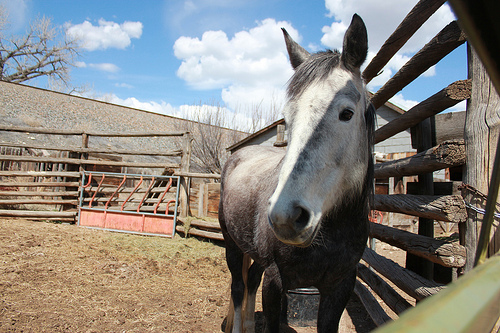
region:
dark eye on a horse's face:
[337, 102, 358, 127]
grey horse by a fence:
[196, 16, 379, 331]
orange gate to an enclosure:
[82, 166, 184, 235]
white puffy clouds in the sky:
[92, 20, 233, 111]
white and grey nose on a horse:
[269, 188, 319, 250]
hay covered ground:
[44, 241, 154, 321]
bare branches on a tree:
[17, 21, 87, 92]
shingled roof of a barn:
[12, 75, 202, 167]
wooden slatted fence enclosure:
[7, 135, 72, 223]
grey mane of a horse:
[289, 42, 339, 100]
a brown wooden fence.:
[0, 120, 84, 225]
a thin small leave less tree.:
[0, 12, 87, 97]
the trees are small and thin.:
[177, 101, 231, 174]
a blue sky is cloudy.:
[165, 23, 272, 95]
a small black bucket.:
[283, 282, 323, 332]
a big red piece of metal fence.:
[77, 167, 177, 240]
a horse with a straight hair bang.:
[279, 47, 341, 102]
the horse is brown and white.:
[215, 9, 382, 331]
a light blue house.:
[365, 88, 415, 158]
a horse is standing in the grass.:
[156, 11, 454, 331]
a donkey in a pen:
[63, 12, 388, 330]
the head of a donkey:
[262, 15, 382, 255]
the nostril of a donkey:
[288, 198, 309, 229]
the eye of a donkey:
[336, 103, 358, 125]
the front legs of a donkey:
[258, 262, 355, 329]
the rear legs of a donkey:
[213, 226, 263, 330]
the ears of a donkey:
[278, 10, 368, 67]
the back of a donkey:
[236, 142, 287, 173]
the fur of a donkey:
[232, 167, 265, 225]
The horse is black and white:
[192, 14, 384, 331]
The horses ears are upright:
[271, 15, 371, 77]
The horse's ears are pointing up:
[269, 10, 375, 80]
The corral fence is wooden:
[280, 16, 497, 284]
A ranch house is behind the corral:
[7, 55, 445, 252]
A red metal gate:
[57, 148, 187, 250]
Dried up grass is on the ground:
[1, 209, 238, 327]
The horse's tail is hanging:
[202, 203, 257, 326]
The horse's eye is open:
[322, 86, 360, 133]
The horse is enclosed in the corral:
[2, 102, 495, 317]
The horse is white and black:
[198, 15, 388, 326]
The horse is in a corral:
[3, 16, 478, 317]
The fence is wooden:
[350, 12, 495, 327]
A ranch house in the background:
[2, 66, 462, 262]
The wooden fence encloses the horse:
[3, 111, 211, 258]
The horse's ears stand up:
[250, 14, 387, 82]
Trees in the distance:
[4, 13, 94, 113]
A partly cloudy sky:
[4, 5, 486, 152]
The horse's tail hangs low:
[215, 222, 265, 329]